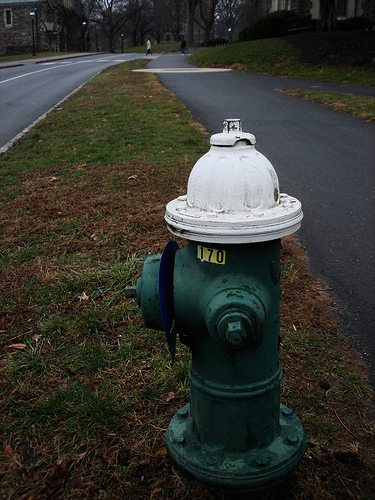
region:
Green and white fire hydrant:
[121, 117, 312, 481]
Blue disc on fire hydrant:
[156, 223, 183, 367]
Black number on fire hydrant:
[195, 240, 225, 264]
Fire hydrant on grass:
[114, 113, 310, 484]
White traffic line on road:
[0, 50, 128, 119]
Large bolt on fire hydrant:
[253, 453, 265, 466]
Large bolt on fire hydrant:
[286, 431, 299, 441]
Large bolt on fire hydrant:
[281, 406, 292, 414]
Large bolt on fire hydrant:
[176, 407, 189, 416]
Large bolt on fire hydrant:
[174, 431, 183, 442]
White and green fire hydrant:
[116, 114, 306, 487]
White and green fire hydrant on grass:
[114, 117, 311, 479]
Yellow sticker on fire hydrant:
[196, 246, 226, 265]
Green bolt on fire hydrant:
[204, 450, 222, 467]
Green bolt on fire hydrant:
[252, 451, 272, 467]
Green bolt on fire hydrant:
[285, 430, 299, 445]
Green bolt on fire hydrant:
[281, 404, 294, 417]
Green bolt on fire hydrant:
[175, 406, 188, 418]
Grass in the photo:
[119, 108, 175, 156]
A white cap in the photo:
[164, 116, 304, 242]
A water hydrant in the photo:
[122, 105, 306, 484]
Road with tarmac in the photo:
[272, 104, 329, 184]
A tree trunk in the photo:
[103, 28, 120, 52]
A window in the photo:
[3, 8, 11, 24]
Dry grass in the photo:
[76, 199, 139, 238]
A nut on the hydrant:
[215, 305, 249, 349]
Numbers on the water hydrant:
[190, 243, 232, 264]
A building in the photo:
[1, 3, 57, 56]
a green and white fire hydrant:
[122, 117, 306, 487]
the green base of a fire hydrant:
[120, 241, 308, 489]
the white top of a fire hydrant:
[163, 117, 305, 245]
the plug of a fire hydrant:
[224, 319, 248, 349]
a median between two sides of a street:
[1, 57, 372, 498]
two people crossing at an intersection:
[143, 32, 190, 57]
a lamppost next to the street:
[81, 19, 86, 53]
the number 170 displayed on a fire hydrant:
[194, 246, 227, 263]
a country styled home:
[0, 0, 99, 53]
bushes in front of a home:
[234, 8, 296, 39]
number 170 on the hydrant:
[195, 244, 231, 269]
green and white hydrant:
[129, 113, 320, 493]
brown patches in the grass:
[97, 361, 146, 403]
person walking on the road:
[138, 36, 157, 57]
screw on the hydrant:
[242, 451, 283, 468]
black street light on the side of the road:
[26, 5, 39, 61]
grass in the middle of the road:
[274, 82, 373, 122]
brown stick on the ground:
[325, 404, 359, 445]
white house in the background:
[266, 3, 371, 21]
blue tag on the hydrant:
[153, 237, 178, 361]